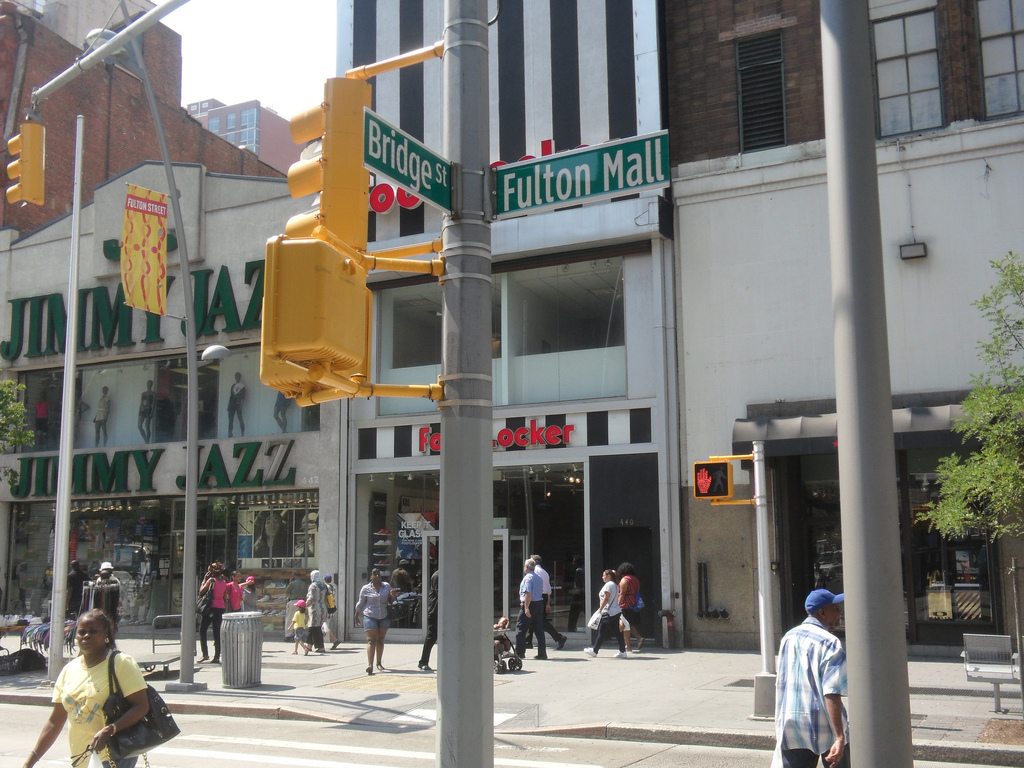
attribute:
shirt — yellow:
[52, 649, 150, 764]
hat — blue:
[799, 584, 858, 613]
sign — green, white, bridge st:
[342, 81, 513, 233]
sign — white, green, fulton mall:
[458, 116, 811, 277]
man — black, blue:
[735, 574, 854, 763]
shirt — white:
[731, 595, 894, 764]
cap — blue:
[761, 559, 887, 640]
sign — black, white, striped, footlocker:
[352, 384, 811, 510]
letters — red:
[394, 405, 682, 472]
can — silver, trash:
[210, 567, 325, 764]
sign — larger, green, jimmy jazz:
[20, 224, 368, 415]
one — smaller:
[3, 380, 371, 532]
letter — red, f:
[379, 419, 459, 486]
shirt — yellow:
[22, 632, 319, 754]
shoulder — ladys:
[83, 634, 181, 717]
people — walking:
[169, 505, 731, 694]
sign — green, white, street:
[480, 97, 764, 264]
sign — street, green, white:
[318, 56, 479, 260]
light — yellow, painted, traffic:
[255, 21, 526, 555]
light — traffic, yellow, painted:
[1, 105, 90, 313]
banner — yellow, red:
[82, 153, 217, 363]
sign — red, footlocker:
[409, 405, 697, 512]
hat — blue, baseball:
[767, 546, 893, 642]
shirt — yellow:
[31, 630, 254, 764]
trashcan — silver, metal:
[182, 583, 310, 731]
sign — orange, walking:
[646, 399, 763, 527]